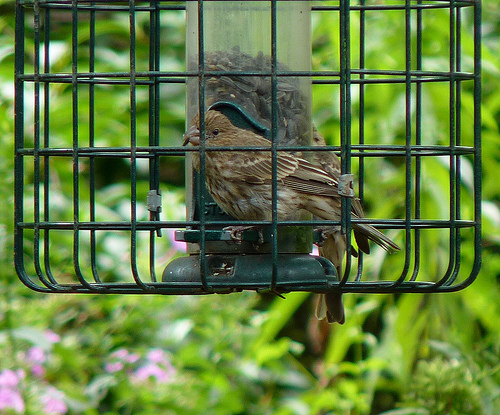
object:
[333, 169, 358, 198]
clip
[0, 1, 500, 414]
photo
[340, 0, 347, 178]
green wire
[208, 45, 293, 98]
birdseed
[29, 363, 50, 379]
flowers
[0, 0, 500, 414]
vegetation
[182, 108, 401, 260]
bird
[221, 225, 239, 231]
claws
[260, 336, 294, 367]
leaves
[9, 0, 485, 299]
cage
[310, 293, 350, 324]
tail feather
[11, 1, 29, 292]
wire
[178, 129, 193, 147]
beak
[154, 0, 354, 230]
door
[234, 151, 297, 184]
feathers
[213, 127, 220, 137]
eye